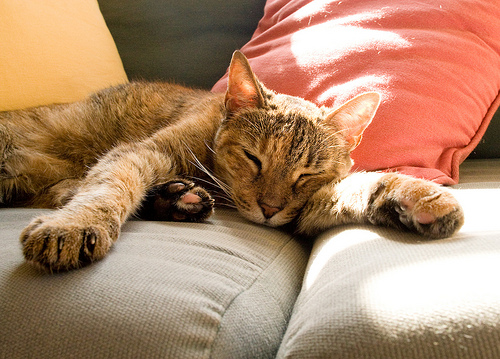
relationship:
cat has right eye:
[2, 49, 464, 272] [294, 167, 324, 194]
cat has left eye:
[2, 49, 464, 272] [244, 146, 263, 182]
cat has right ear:
[2, 49, 464, 272] [325, 89, 381, 147]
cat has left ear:
[2, 49, 464, 272] [226, 48, 268, 108]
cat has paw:
[2, 49, 464, 272] [377, 173, 467, 237]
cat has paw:
[2, 49, 464, 272] [19, 210, 118, 271]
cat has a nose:
[2, 49, 464, 272] [260, 198, 282, 218]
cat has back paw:
[2, 49, 464, 272] [134, 178, 216, 222]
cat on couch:
[2, 49, 464, 272] [0, 2, 499, 357]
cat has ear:
[2, 49, 464, 272] [226, 48, 268, 108]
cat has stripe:
[2, 49, 464, 272] [288, 122, 304, 155]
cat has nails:
[2, 49, 464, 272] [43, 234, 102, 249]